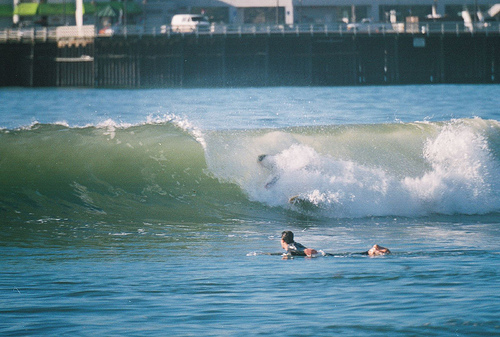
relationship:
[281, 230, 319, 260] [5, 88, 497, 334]
man in water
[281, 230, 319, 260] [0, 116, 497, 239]
man looking at a wave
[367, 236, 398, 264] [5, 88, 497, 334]
feet in water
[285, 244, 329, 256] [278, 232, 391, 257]
wetsuit on man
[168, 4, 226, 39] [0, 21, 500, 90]
van on boardwalk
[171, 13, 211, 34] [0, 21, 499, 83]
van on boardwalk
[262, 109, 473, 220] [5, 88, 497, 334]
wave crashing in water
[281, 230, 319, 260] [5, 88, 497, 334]
man swimming in water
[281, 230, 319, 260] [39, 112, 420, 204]
man ready to catch wave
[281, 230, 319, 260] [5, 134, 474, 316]
man paddling on water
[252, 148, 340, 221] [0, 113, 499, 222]
person on wave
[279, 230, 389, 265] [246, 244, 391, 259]
man on board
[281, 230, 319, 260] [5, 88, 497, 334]
man paddling in water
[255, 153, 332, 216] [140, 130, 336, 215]
person in wave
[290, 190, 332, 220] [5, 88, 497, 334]
board in water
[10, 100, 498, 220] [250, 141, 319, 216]
wave swallowing surfer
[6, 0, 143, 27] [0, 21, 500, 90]
umbrellas on boardwalk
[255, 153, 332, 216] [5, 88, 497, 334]
person swimming water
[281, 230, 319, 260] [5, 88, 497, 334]
man swimming water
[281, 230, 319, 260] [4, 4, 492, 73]
man close to city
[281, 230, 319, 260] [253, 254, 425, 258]
man on board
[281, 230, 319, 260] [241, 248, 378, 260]
man laying on board